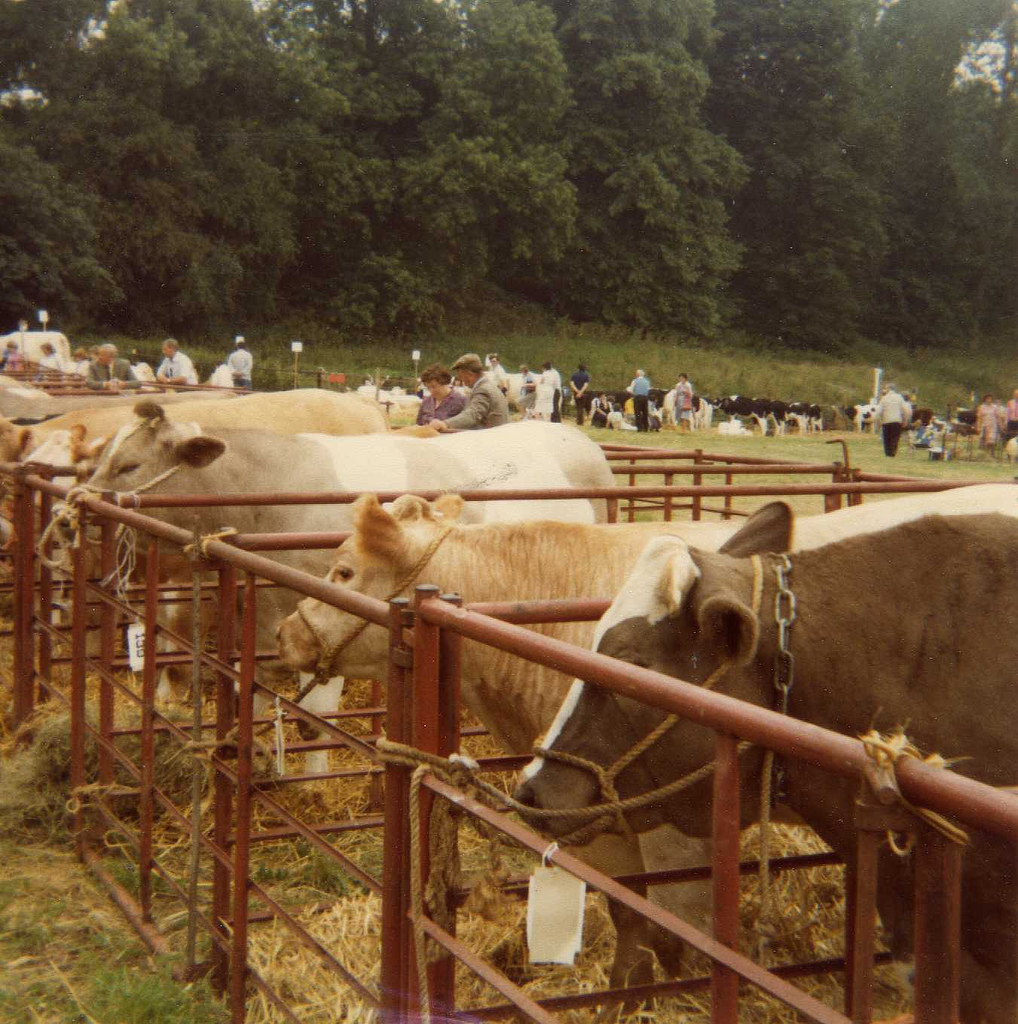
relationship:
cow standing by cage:
[402, 498, 1016, 1019] [383, 576, 1004, 1016]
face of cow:
[502, 569, 735, 813] [516, 487, 1015, 1020]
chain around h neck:
[742, 524, 808, 827] [742, 528, 912, 827]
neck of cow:
[742, 528, 912, 827] [516, 487, 1015, 1020]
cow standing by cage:
[272, 506, 768, 987] [379, 582, 1016, 1020]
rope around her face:
[261, 539, 446, 690] [276, 509, 424, 671]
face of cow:
[276, 509, 424, 671] [272, 491, 812, 1020]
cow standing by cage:
[50, 391, 631, 787] [379, 582, 1016, 1020]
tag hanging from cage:
[513, 854, 601, 994] [379, 582, 1016, 1020]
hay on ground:
[72, 680, 890, 1020] [6, 335, 1001, 1019]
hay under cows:
[72, 680, 890, 1020] [6, 387, 1012, 1008]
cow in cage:
[511, 477, 1017, 1021] [379, 582, 1016, 1020]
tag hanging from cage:
[522, 860, 590, 966] [379, 582, 1016, 1020]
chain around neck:
[769, 546, 799, 811] [742, 538, 888, 839]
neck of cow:
[742, 538, 888, 839] [516, 487, 1015, 1020]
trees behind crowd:
[1, 3, 1015, 354] [12, 303, 1017, 458]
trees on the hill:
[225, 57, 930, 310] [500, 312, 709, 371]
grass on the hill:
[612, 342, 687, 362] [608, 331, 769, 390]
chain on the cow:
[769, 546, 799, 811] [532, 507, 981, 786]